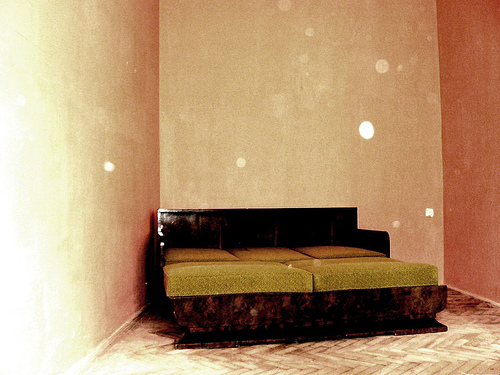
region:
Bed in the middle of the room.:
[148, 199, 453, 348]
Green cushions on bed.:
[171, 242, 443, 297]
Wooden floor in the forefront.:
[100, 294, 497, 374]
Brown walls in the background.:
[161, 4, 453, 206]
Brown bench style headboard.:
[152, 205, 389, 283]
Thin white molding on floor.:
[447, 280, 498, 312]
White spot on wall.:
[354, 120, 378, 144]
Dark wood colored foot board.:
[165, 285, 450, 352]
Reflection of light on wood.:
[154, 204, 171, 250]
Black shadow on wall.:
[136, 209, 158, 321]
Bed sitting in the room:
[125, 143, 465, 362]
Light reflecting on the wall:
[341, 92, 384, 149]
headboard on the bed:
[139, 182, 428, 263]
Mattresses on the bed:
[128, 234, 438, 314]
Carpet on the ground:
[250, 344, 317, 370]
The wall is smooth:
[44, 108, 91, 158]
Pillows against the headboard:
[167, 228, 449, 284]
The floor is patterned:
[236, 339, 275, 371]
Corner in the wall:
[413, 153, 498, 288]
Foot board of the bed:
[152, 276, 496, 341]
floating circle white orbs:
[287, 15, 415, 158]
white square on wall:
[418, 200, 441, 230]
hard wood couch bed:
[137, 192, 462, 346]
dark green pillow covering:
[166, 238, 455, 298]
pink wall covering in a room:
[419, 69, 490, 267]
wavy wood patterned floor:
[342, 344, 437, 371]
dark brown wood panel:
[169, 292, 406, 352]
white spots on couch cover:
[277, 249, 332, 281]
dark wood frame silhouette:
[322, 205, 397, 251]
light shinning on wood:
[147, 201, 194, 244]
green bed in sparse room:
[133, 198, 453, 342]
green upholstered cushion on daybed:
[165, 252, 312, 294]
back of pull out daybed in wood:
[158, 200, 395, 252]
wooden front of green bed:
[173, 282, 449, 352]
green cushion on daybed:
[296, 246, 438, 287]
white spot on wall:
[425, 207, 440, 220]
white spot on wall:
[358, 118, 378, 145]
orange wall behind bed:
[155, 1, 445, 368]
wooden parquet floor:
[105, 275, 499, 367]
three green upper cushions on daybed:
[171, 233, 380, 263]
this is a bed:
[180, 214, 369, 352]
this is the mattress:
[208, 268, 283, 296]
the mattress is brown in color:
[214, 263, 273, 285]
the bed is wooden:
[161, 215, 301, 233]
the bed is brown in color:
[184, 217, 308, 272]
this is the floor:
[381, 349, 441, 373]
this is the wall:
[321, 97, 404, 155]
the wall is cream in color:
[256, 79, 385, 144]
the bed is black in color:
[193, 221, 265, 250]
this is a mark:
[352, 108, 390, 142]